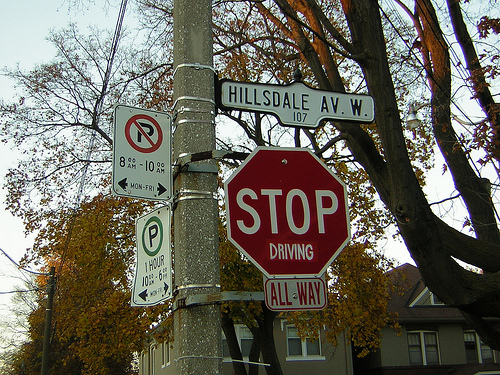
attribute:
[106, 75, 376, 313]
signs — touching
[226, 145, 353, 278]
sign — red, octagon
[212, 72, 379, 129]
sign — white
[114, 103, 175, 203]
sign — white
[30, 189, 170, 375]
tree — yellow, large, standing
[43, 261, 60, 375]
pole — standing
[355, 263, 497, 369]
house — behind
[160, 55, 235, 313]
clamps — metal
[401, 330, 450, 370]
window — closed, glass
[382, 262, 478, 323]
roof — brown